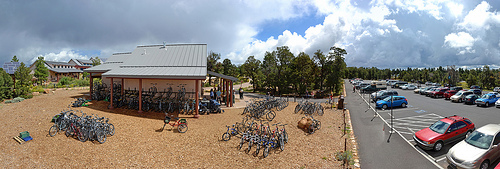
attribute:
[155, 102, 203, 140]
bike — red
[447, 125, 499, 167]
car — gold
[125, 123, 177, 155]
ground — tan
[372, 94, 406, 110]
car — blue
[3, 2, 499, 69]
sky — cloudy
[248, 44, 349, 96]
leaves — green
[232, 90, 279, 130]
man — white